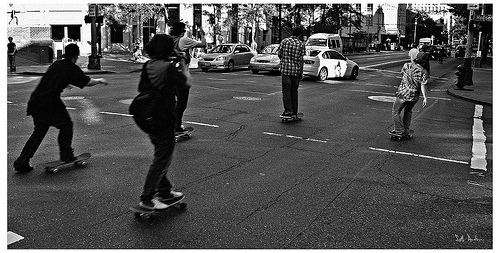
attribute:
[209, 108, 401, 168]
lines — white, straight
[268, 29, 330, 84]
shirt — plaid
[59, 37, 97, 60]
cap — black, here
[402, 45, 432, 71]
scarf — white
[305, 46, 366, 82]
car — here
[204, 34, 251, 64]
automobile — silver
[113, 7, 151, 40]
tree — large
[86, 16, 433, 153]
people — skating, riding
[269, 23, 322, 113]
person — skating, here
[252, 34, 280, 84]
vehicle — here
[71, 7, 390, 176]
photo — black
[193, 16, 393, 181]
picture — white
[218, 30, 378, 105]
cars — here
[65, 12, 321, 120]
skateboarders — wearing, unprotected, crossing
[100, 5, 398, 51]
buildings — lining, here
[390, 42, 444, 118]
man — here, light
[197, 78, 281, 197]
road — here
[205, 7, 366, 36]
trees — here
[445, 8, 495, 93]
pole — here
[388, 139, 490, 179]
line — white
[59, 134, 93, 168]
shoe — here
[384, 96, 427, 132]
trouser — here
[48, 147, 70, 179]
skateboard — here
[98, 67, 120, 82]
hand — here